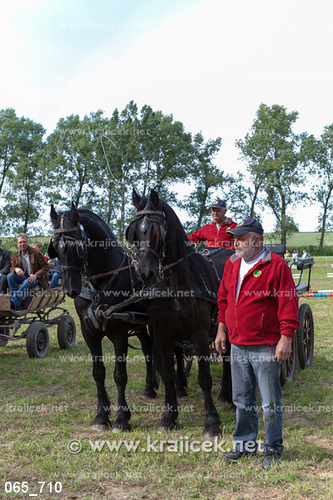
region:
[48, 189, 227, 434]
Two dark brown horses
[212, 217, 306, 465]
Man standing next to two horses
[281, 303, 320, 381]
Wheels of a horse drawn carriage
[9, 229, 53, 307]
A man watching two horses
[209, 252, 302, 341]
Red fleece jacket on a man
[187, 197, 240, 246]
A man riding in a horse drawn carriage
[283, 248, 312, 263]
People at a park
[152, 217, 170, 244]
Horse blinders so they aren't easily startled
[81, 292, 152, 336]
Front hardware of a horse drawn carriage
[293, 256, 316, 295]
Hand rail of horse drawn carriage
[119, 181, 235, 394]
black horse hooked to carriage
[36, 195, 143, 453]
black horse hooked to carriage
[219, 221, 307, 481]
man in red coat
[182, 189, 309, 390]
man sitting on carriage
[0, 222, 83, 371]
wooden wagon carrying people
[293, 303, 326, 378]
brown wagon wheel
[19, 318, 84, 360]
black tires on metal wheels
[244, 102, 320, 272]
trees with green leaves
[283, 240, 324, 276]
people watching from a distance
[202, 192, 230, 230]
man wearing blue hat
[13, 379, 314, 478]
the grass is green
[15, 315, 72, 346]
the wheels are on buggy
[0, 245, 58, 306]
family is in the buggy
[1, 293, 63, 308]
the buggy is brown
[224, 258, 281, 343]
the jacket is red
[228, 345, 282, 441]
the jeans are blue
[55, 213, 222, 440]
the horses are black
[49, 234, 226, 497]
the horses in the grass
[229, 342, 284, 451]
the jeans are made of denim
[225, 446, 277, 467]
the shoes are black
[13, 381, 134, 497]
grass is green and brown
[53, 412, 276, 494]
grass is green and brown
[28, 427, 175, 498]
grass is green and brown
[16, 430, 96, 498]
grass is green and brown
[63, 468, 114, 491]
grass is green and brown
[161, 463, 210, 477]
grass is green and brown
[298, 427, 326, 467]
grass is green and brown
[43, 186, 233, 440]
a pair of black horses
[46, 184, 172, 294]
the horses have blinders on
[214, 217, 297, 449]
a man is wearing dungarees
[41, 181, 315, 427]
the horses are pulling a wagon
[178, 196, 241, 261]
the driver of the horse drawn cart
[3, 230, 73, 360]
a man sitting on a cart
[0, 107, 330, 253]
green trees are in the background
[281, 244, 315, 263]
a group of people in the background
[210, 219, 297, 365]
the man is wearing a red fleece jacket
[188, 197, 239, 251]
the driver is wearing a black cap